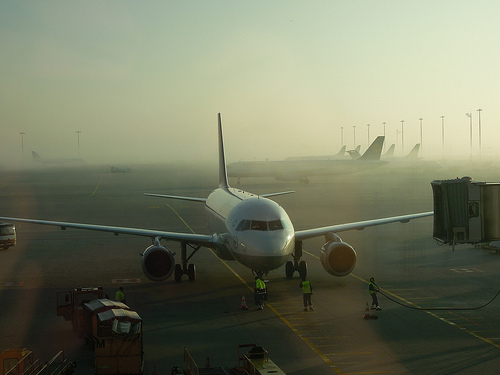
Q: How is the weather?
A: Hazy.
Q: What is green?
A: Safety vests.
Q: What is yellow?
A: Lines on the ground.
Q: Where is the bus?
A: To the left of the plane.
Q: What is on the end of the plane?
A: Tail.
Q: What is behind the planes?
A: Poles.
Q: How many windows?
A: Three.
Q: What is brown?
A: Luggage cart.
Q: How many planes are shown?
A: 7.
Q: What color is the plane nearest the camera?
A: White.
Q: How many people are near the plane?
A: 4.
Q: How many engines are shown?
A: 2.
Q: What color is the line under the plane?
A: Yellow.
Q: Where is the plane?
A: Tarmac.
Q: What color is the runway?
A: Black.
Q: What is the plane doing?
A: Taxiing.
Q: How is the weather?
A: It is foggy.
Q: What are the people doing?
A: Directing the plan.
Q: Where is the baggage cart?
A: To the left of the plane.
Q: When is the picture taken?
A: In the morning.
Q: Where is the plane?
A: On the taxiway.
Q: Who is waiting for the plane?
A: The people.